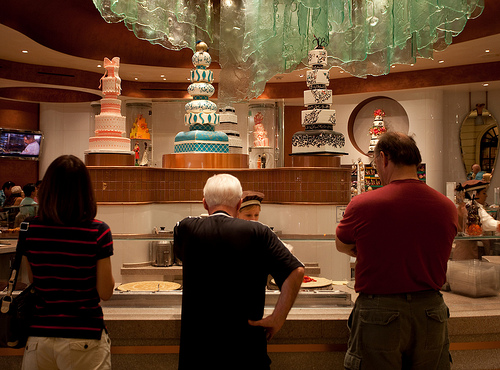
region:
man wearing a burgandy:
[394, 221, 418, 250]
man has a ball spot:
[392, 130, 409, 137]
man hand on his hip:
[254, 260, 292, 336]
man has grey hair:
[207, 173, 237, 200]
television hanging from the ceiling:
[6, 123, 45, 156]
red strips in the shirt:
[97, 228, 107, 243]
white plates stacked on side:
[461, 253, 497, 298]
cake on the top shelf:
[184, 63, 224, 148]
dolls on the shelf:
[132, 107, 150, 161]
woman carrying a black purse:
[6, 292, 28, 344]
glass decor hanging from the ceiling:
[93, 1, 496, 114]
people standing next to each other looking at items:
[13, 128, 461, 368]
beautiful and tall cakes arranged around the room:
[81, 37, 350, 157]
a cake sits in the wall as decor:
[351, 101, 406, 158]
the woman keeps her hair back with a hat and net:
[236, 188, 271, 224]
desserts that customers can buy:
[105, 270, 357, 301]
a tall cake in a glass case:
[244, 103, 281, 150]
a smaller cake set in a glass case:
[125, 88, 155, 168]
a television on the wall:
[2, 125, 50, 164]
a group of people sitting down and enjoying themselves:
[3, 177, 50, 222]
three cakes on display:
[85, 40, 377, 180]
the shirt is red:
[317, 173, 466, 326]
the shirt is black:
[159, 211, 356, 357]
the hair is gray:
[180, 155, 251, 212]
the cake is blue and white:
[173, 29, 265, 159]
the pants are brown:
[335, 253, 444, 356]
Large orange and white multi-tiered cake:
[77, 48, 139, 167]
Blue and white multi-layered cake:
[166, 35, 243, 165]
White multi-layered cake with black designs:
[287, 32, 353, 163]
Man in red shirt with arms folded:
[332, 133, 462, 368]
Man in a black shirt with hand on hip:
[159, 173, 306, 369]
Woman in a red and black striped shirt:
[13, 153, 125, 368]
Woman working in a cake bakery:
[454, 174, 499, 232]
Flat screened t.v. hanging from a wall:
[0, 127, 47, 164]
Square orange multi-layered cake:
[125, 113, 155, 143]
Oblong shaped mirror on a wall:
[454, 100, 499, 187]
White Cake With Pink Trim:
[89, 58, 132, 155]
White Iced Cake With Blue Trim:
[166, 40, 228, 151]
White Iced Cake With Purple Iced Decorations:
[293, 37, 343, 155]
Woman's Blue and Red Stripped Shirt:
[17, 217, 110, 340]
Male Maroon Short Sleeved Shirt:
[336, 177, 468, 306]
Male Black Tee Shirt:
[160, 205, 304, 368]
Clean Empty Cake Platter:
[113, 271, 182, 308]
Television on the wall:
[3, 126, 50, 158]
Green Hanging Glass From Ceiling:
[89, 2, 483, 84]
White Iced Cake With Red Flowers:
[356, 98, 401, 151]